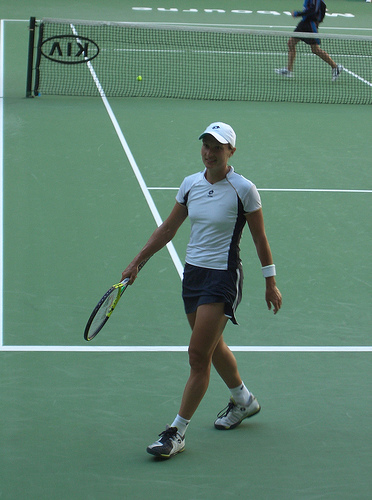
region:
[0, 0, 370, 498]
tennis player in a tennis court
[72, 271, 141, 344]
a blue and green racket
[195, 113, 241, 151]
a white cap on head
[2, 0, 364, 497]
floor of tennis court is green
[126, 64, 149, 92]
a ball on the floor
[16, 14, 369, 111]
net of tennis is black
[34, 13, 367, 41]
border of net is color white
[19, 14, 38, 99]
pole of net is black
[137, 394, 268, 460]
a pair of white and and blue shoes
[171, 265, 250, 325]
shorts are blue with white stripes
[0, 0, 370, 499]
tennis court in use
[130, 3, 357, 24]
name on tennis court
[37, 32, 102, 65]
Kia name and logo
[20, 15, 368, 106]
tennis net dividing court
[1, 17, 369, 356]
white boundary lines on court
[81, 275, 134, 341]
tennis racket in woman's right hand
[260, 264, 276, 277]
white sweatband on woman's left wrist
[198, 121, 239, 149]
ball cap on woman's head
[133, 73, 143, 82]
green tennis ball on court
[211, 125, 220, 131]
brand logo on cap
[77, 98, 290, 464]
a woman playing tennis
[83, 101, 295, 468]
a woman on the tennis court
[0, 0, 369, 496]
green tennis court with white strips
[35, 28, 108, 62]
the kia logo backwards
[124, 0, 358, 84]
man chasing after a ball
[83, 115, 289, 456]
tennis player with white hat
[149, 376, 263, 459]
the white shoes of the woman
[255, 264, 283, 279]
the white wristband of the woman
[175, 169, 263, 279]
the white shirt of the woman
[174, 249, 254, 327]
the black shorts of the woman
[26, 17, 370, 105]
A black and white tennis net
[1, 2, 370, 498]
A tennis court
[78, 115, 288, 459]
A person holding a tennis racket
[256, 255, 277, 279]
A white wrist band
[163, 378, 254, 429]
A pair of white above the ankle socks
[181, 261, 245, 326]
A pair of black sports shorts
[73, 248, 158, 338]
A tennis racket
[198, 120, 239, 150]
A white ball cap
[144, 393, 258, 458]
A pair of black and grey tennis shoes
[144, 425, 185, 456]
black and white tennis shoes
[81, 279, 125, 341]
the black and yellow tennis racquet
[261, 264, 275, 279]
a white wrist band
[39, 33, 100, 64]
the name brand logo on the tennis net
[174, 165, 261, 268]
a black and white tennis shirt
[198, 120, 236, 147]
a white tennis cap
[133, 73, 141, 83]
a fluorescent yellow tennis ball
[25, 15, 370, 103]
a tennis net on the court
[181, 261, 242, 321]
black tennis shorts with a white stripe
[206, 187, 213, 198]
the logo brand name on the shirt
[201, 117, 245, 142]
The cap is white.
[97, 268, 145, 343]
Woman holding tennis racket.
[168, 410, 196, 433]
The sock is white.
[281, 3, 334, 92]
A person running on the court.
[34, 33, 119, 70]
The word Kia written on the net.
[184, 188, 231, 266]
The front of shirt is white.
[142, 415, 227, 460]
Person is wearing sneakers.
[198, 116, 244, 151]
a man wearing a white hat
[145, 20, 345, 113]
a black and white tennis net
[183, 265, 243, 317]
a man wearing blue shorts with a white stripe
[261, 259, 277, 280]
a man wearing a white wrist band